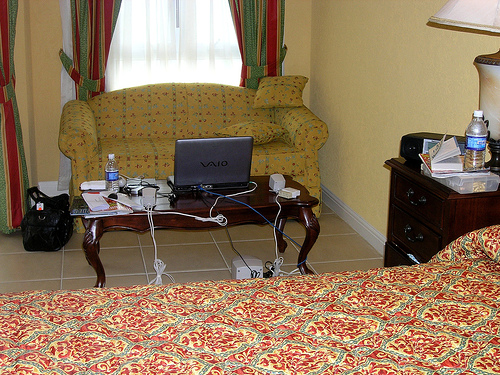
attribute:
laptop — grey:
[169, 135, 251, 190]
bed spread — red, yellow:
[160, 261, 440, 362]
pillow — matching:
[213, 118, 289, 146]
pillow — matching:
[254, 73, 306, 110]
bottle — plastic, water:
[462, 104, 494, 174]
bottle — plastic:
[464, 109, 496, 184]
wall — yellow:
[313, 7, 387, 224]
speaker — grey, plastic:
[259, 167, 316, 204]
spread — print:
[1, 224, 498, 374]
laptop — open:
[163, 139, 257, 196]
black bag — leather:
[22, 182, 71, 251]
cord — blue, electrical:
[193, 186, 310, 296]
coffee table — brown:
[77, 170, 321, 290]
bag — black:
[20, 185, 72, 250]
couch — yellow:
[47, 73, 329, 231]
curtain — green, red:
[1, 1, 34, 234]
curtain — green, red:
[57, 1, 123, 96]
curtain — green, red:
[227, 1, 287, 90]